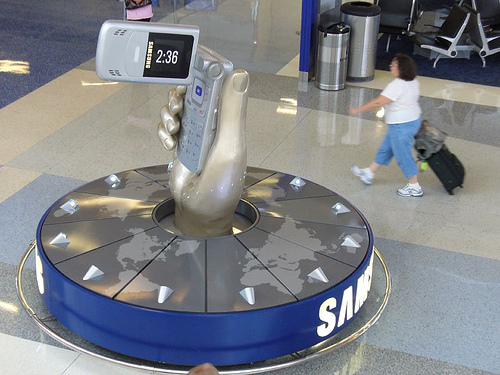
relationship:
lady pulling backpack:
[344, 52, 426, 202] [416, 117, 466, 198]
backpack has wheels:
[416, 117, 466, 198] [446, 184, 463, 196]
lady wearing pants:
[344, 52, 426, 202] [377, 115, 421, 181]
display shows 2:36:
[19, 18, 393, 371] [155, 48, 181, 65]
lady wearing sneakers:
[344, 52, 426, 202] [350, 165, 427, 200]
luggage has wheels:
[416, 117, 466, 198] [446, 184, 463, 196]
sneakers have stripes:
[350, 165, 427, 200] [399, 187, 424, 192]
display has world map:
[19, 18, 393, 371] [72, 169, 366, 307]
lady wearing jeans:
[344, 52, 426, 202] [377, 115, 421, 181]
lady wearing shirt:
[344, 52, 426, 202] [382, 78, 421, 125]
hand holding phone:
[157, 69, 251, 238] [93, 17, 235, 177]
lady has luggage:
[344, 52, 426, 202] [416, 117, 466, 198]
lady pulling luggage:
[344, 52, 426, 202] [416, 117, 466, 198]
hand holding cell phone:
[157, 69, 251, 238] [93, 17, 235, 177]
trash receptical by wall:
[312, 0, 386, 94] [302, 1, 349, 72]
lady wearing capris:
[344, 52, 426, 202] [377, 115, 421, 181]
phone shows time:
[93, 17, 235, 177] [155, 48, 181, 65]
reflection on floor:
[267, 86, 304, 122] [7, 79, 170, 199]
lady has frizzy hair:
[344, 52, 426, 202] [398, 53, 417, 81]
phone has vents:
[93, 17, 235, 177] [108, 27, 134, 77]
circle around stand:
[16, 237, 392, 374] [35, 219, 377, 367]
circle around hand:
[148, 197, 262, 242] [157, 69, 251, 238]